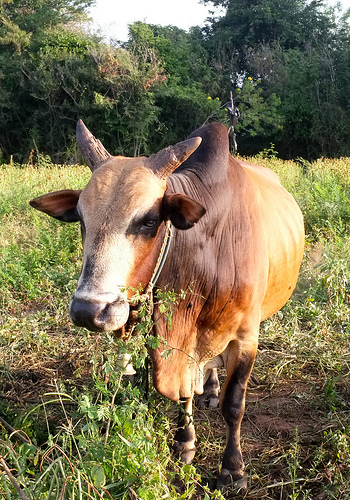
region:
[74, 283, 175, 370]
brown boar eating plants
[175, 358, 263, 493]
dark brown legs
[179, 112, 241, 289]
dark brown hump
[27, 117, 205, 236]
light brown horns and dark brown ears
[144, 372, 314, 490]
patch of brown under boar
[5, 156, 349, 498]
mix of green, yellow, and brown grass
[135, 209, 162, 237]
black patches around eyes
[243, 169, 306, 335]
sunlight reflects on back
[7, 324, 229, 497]
wild unkempt bushes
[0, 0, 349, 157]
tall trees behind grass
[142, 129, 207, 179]
the horn of the cow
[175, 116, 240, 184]
this animal has a hump on its back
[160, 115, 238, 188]
the hump is dark brown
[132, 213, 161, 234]
its eyes are black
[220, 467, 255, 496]
its hoof is black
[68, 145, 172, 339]
his head is white black and brown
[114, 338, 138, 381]
the bell is behind the bush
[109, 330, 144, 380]
the bell is attached to the rope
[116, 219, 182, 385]
the bell hangs from a rope around the animals neck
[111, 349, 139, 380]
the bell is silver in color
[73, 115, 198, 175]
the cow's horns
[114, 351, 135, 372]
the cow bell hanging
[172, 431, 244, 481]
the front feet of the cow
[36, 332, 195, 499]
the tall greenery by the cow's face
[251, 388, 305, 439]
the dirt on on the ground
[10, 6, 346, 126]
the tall trees behind the cow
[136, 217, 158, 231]
the cow's left eye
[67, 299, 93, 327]
the cow's wet nose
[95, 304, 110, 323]
the cow's nostril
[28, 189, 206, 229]
the cow's ears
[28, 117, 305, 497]
A big bull with horns.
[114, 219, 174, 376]
A bell on a rope.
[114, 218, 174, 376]
A bell on a cow.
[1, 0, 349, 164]
Green trees behind the bull.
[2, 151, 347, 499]
Grass and weeds on the ground.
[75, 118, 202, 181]
Two horns on a bull.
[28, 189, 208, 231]
Two ears on a bull.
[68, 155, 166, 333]
A bull's head and face.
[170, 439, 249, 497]
A bull's two front hoofs.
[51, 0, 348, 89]
Blue sky between the trees.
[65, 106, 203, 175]
two short pointed horns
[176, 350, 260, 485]
legs are covered with darker hide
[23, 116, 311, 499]
a zebu cow stands alone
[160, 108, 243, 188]
hump of muscle and fatty tissue on shoulders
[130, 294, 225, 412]
a long dewlap attached to the lower jaw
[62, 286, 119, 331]
a wide wet nose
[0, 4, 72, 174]
trees edge the meadow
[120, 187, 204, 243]
the left eye is shadowed by the left ear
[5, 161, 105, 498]
long weeds of a meadow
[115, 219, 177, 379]
a cow bell attached to a rope